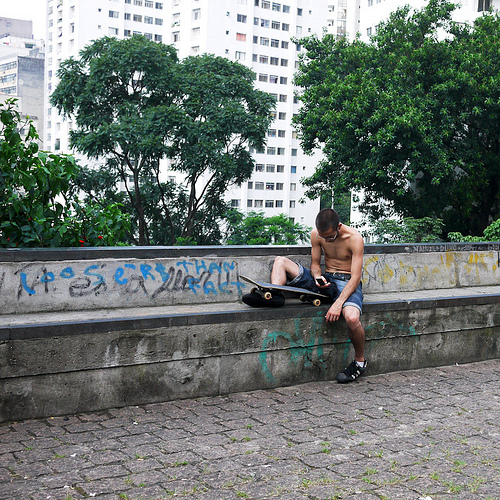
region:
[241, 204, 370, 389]
the man sitting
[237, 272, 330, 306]
the skateboard near the man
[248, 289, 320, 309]
the wheels on the skateboard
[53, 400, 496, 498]
the grass growing through concrete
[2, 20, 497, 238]
the tall green trees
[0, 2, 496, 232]
the big building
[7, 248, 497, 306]
the graffiti on the concrete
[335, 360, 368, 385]
the shoe on the man's left foot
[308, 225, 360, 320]
the man's two arms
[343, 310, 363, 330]
the man's left knee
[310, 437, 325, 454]
part of a floor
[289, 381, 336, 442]
part of a floor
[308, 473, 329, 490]
part of a grass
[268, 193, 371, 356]
shirtless man sitting on wall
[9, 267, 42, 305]
black and blue graffiti on wall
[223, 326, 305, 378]
black and blue graffiti on wall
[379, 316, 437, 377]
black and blue graffiti on wall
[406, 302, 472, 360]
black and blue graffiti on wall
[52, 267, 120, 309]
black and blue graffiti on wall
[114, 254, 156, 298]
black and blue graffiti on wall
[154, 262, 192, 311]
black and blue graffiti on wall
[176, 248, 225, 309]
black and blue graffiti on wall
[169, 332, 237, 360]
black and blue graffiti on wall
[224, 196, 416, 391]
Man sitting down with a skateboard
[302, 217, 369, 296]
man does not have a shirt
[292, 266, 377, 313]
man is wearing blue shorts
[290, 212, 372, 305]
man is on his phone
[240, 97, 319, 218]
white building in the back ground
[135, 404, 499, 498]
plants growing through brick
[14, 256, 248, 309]
blue graffiti on the wall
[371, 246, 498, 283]
orange graffiti on wall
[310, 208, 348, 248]
man has glasses on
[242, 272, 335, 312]
yellow wheels on skateboard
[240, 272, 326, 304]
a black skateboard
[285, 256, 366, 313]
a man's blue jean shorts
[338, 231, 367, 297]
the arm of a man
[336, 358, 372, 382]
a man's tennis shoe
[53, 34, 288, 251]
a large green tree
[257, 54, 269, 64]
a window of a building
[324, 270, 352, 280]
a man's black belt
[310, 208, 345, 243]
the head of a man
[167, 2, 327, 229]
a tall white building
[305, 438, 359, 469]
a gray brick